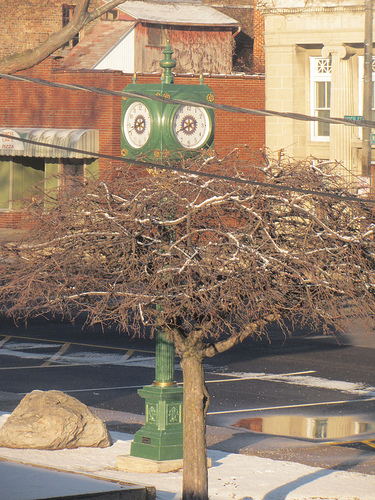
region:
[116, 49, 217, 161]
Two clocks next to each other.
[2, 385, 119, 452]
A big gray rock.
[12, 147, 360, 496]
A tree without any leaves.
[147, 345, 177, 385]
Part of a green pole.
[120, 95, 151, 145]
A clock attached to a green pole.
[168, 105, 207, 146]
Another clock attached to the green pole.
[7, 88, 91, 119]
Red bricks on a building.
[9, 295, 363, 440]
A street by the clock.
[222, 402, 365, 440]
A water puddle in the street.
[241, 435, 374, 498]
The shadow of a tree.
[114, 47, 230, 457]
A tall green clock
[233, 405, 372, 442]
A water puddle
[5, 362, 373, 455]
An area marked for parking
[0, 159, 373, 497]
A tree with a bit of snow on it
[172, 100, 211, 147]
A white clock face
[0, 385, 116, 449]
A rock to keep peple from parking there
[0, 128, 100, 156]
An awning over a window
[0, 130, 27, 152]
The name of a pizza place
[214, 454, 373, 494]
A bit of snow on the ground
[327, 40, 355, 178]
A pillar on a building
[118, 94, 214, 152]
Two clock faces visible.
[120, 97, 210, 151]
Clock faces are white.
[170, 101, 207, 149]
Twelve numbers on clock.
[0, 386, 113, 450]
The rock is brown.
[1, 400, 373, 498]
Snow covering the ground.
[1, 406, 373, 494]
The snow is white.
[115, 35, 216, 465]
Clock tower is green.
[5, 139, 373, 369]
The tree is bare.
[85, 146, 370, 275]
snow covering the tree.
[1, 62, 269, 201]
The bricks are red.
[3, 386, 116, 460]
large boulder beside parking lot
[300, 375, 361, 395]
snow laying on pavement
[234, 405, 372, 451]
standing water in parking lot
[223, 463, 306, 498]
snow covering ground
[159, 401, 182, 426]
design on side of green clock pole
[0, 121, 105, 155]
awning over store entrance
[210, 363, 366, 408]
white lines on parking lot pavement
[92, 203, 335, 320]
brown tree with snow on limbs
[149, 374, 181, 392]
gold ring around clock pole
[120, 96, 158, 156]
large clock on green pole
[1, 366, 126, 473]
very large rock on the sidewalk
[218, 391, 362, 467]
large water puddle in a parking lot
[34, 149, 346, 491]
large brown tree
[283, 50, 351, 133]
white window on the front of a building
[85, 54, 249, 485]
green clock with the number 1 on it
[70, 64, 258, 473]
green clock with the number 2 on it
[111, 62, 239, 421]
green clock with the number 3 on it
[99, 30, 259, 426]
green clock with the number 4 on it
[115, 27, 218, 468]
green clock with the number 5 on it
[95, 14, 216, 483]
green clock with the number 6 on it